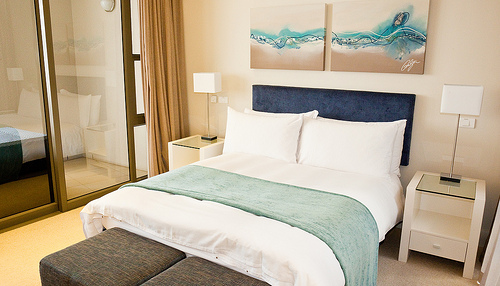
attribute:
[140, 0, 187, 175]
curtain — tan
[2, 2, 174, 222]
door — sliding, glass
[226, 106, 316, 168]
pillow — white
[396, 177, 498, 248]
table — wooden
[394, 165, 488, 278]
table — wooden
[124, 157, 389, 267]
blanket — green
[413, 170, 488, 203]
table top — glass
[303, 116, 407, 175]
pillow — white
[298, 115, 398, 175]
pillow — white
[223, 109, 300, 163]
pillow — white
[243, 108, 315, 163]
pillow — white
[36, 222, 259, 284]
ottomans — gray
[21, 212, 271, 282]
bench — gray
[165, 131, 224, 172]
nightstand — white